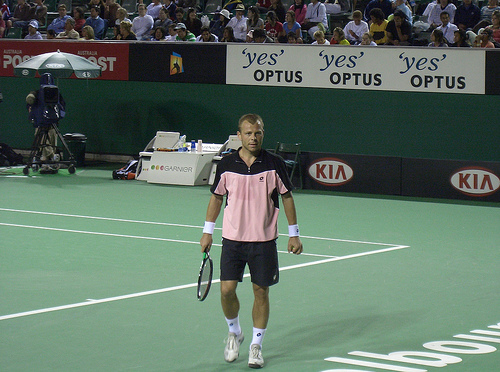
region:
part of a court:
[345, 290, 397, 340]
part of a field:
[330, 290, 365, 322]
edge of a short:
[252, 274, 278, 293]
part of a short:
[245, 242, 264, 259]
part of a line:
[89, 280, 132, 316]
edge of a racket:
[184, 260, 211, 307]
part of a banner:
[422, 134, 482, 206]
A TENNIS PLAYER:
[191, 108, 308, 370]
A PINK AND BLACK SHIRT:
[191, 146, 296, 248]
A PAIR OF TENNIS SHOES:
[201, 330, 289, 369]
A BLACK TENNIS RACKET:
[194, 226, 220, 310]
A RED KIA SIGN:
[300, 144, 375, 195]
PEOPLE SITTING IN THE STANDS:
[146, 4, 421, 47]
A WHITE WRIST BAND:
[194, 210, 222, 242]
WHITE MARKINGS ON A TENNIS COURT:
[1, 199, 192, 331]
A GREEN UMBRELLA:
[9, 46, 114, 89]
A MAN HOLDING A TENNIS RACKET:
[124, 103, 372, 368]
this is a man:
[192, 122, 290, 365]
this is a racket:
[193, 257, 214, 302]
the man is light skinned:
[207, 199, 217, 211]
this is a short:
[249, 248, 272, 280]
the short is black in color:
[255, 255, 272, 262]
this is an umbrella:
[31, 51, 96, 77]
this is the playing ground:
[43, 207, 134, 338]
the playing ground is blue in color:
[362, 262, 397, 319]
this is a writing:
[247, 70, 469, 92]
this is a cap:
[27, 17, 40, 24]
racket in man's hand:
[175, 232, 225, 303]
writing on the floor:
[423, 302, 488, 368]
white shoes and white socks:
[208, 318, 275, 360]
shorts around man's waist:
[210, 231, 283, 303]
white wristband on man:
[285, 209, 310, 255]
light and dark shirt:
[203, 149, 295, 228]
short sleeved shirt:
[182, 135, 292, 251]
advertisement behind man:
[286, 141, 366, 219]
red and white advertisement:
[303, 148, 362, 204]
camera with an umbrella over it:
[16, 43, 103, 170]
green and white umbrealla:
[12, 44, 104, 79]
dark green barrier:
[3, 76, 496, 181]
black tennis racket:
[197, 248, 212, 300]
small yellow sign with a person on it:
[167, 49, 184, 75]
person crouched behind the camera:
[23, 88, 56, 163]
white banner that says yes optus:
[223, 42, 483, 93]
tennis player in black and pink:
[199, 111, 303, 366]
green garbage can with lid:
[63, 128, 84, 163]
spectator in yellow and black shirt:
[367, 7, 390, 42]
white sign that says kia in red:
[305, 156, 355, 186]